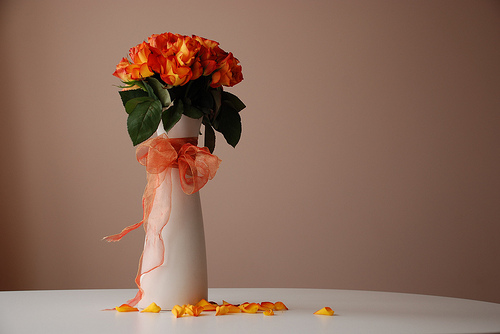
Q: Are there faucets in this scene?
A: No, there are no faucets.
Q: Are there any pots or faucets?
A: No, there are no faucets or pots.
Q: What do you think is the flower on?
A: The flower is on the table.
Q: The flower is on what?
A: The flower is on the table.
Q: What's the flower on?
A: The flower is on the table.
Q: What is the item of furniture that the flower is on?
A: The piece of furniture is a table.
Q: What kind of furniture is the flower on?
A: The flower is on the table.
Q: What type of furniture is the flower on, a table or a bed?
A: The flower is on a table.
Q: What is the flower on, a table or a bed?
A: The flower is on a table.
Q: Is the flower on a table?
A: Yes, the flower is on a table.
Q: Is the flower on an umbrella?
A: No, the flower is on a table.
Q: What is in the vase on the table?
A: The flower is in the vase.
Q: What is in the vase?
A: The flower is in the vase.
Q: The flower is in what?
A: The flower is in the vase.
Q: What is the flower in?
A: The flower is in the vase.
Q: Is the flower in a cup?
A: No, the flower is in the vase.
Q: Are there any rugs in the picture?
A: No, there are no rugs.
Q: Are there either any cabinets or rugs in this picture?
A: No, there are no rugs or cabinets.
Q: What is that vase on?
A: The vase is on the table.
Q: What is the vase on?
A: The vase is on the table.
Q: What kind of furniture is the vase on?
A: The vase is on the table.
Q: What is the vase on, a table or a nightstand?
A: The vase is on a table.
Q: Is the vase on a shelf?
A: No, the vase is on the table.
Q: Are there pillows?
A: No, there are no pillows.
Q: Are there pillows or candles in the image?
A: No, there are no pillows or candles.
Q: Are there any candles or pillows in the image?
A: No, there are no pillows or candles.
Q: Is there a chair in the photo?
A: No, there are no chairs.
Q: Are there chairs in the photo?
A: No, there are no chairs.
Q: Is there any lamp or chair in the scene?
A: No, there are no chairs or lamps.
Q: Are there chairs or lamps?
A: No, there are no chairs or lamps.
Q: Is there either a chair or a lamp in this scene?
A: No, there are no chairs or lamps.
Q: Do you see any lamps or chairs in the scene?
A: No, there are no chairs or lamps.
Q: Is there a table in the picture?
A: Yes, there is a table.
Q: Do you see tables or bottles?
A: Yes, there is a table.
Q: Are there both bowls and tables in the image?
A: No, there is a table but no bowls.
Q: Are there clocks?
A: No, there are no clocks.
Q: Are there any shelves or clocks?
A: No, there are no clocks or shelves.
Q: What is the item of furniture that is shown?
A: The piece of furniture is a table.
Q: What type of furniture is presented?
A: The furniture is a table.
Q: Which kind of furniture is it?
A: The piece of furniture is a table.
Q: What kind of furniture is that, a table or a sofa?
A: This is a table.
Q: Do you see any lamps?
A: No, there are no lamps.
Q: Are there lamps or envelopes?
A: No, there are no lamps or envelopes.